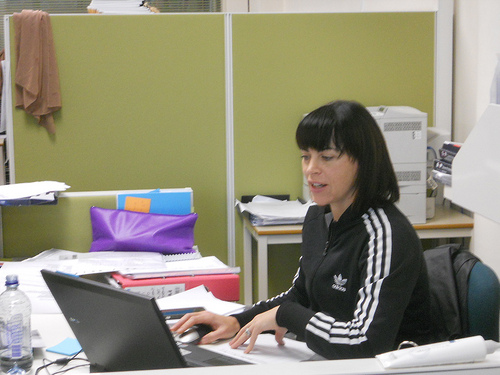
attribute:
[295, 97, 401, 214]
hair — dark, shoulder length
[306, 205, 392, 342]
stripes — white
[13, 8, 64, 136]
sweater — orange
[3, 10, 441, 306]
wall — green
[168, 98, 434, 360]
woman — working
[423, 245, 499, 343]
chair — blue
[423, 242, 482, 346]
coat — black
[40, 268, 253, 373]
laptop — black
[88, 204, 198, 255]
bag — purple, small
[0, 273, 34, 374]
bottle — clear, plastic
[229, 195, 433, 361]
jacket — black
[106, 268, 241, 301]
binder — pink, red